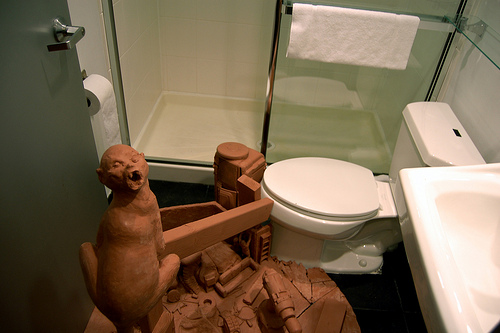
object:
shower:
[107, 0, 464, 195]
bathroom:
[0, 1, 499, 332]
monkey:
[78, 142, 177, 333]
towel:
[287, 4, 420, 73]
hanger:
[276, 0, 466, 35]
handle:
[46, 14, 86, 52]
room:
[0, 0, 497, 333]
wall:
[429, 6, 492, 330]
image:
[0, 0, 497, 333]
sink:
[387, 166, 498, 332]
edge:
[387, 163, 442, 333]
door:
[0, 0, 112, 333]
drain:
[260, 140, 272, 149]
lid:
[262, 156, 383, 224]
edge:
[291, 198, 356, 241]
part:
[163, 192, 275, 285]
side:
[257, 223, 385, 276]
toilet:
[257, 99, 484, 275]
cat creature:
[78, 143, 180, 332]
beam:
[160, 195, 272, 262]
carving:
[74, 140, 361, 332]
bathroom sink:
[393, 162, 499, 333]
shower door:
[259, 1, 465, 180]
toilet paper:
[80, 72, 122, 149]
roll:
[85, 98, 92, 107]